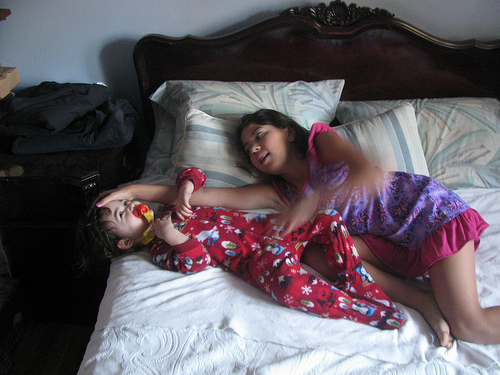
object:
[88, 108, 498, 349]
girl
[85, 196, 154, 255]
head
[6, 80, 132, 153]
sheet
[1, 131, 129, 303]
nightstand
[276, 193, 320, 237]
hand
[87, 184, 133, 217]
hand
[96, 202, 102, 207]
nail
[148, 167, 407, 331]
pajamas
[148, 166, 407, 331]
one piece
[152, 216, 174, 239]
hand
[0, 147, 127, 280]
dark table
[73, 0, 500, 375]
bed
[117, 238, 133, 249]
ear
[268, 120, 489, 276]
dress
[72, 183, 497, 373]
spread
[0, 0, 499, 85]
wall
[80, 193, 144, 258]
hair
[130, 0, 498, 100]
headboard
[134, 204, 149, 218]
pacifier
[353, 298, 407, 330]
foot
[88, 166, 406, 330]
baby